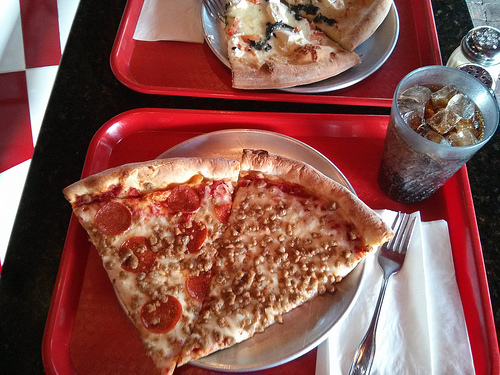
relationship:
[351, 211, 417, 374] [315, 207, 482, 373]
fork and napkin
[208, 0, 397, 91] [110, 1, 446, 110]
food on tray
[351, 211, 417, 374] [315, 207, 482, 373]
fork on napkin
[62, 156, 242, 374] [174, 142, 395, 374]
pizza in slice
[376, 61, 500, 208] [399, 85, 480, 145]
drink with ice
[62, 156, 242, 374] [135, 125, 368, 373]
pizza on plate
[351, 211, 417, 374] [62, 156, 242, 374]
fork near pizza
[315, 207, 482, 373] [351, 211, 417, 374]
napkin under fork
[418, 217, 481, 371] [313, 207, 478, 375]
part of napkin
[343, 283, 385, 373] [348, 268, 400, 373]
part of handle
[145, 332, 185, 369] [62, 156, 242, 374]
tip of pizza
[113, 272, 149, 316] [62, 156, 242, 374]
edge of pizza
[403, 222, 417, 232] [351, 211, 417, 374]
part of fork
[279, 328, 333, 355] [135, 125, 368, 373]
edge of plate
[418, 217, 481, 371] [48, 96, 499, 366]
part of tray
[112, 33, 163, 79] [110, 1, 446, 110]
edge of tray